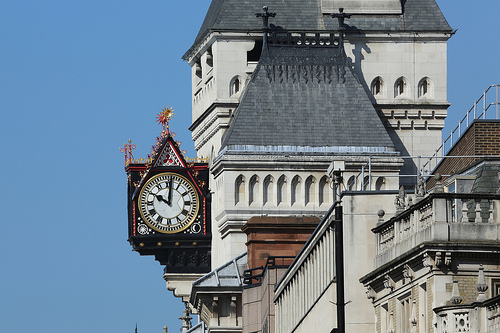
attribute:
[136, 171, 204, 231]
clock — black, white, gold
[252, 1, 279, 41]
cross — black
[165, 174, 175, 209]
hand — black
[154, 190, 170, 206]
hand — black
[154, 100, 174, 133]
decorations — yellow, red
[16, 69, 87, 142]
sky — clear, blue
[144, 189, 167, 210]
hour hand — black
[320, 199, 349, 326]
pole — black, tall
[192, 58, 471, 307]
building — tall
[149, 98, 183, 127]
item — gold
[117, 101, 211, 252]
clock — LARGE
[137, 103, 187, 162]
top — POINTED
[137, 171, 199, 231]
ring — GOLD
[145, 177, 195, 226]
numbers — BLACK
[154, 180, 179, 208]
arms — BLACK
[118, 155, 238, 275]
clock hands — black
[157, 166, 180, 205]
minute hand — black